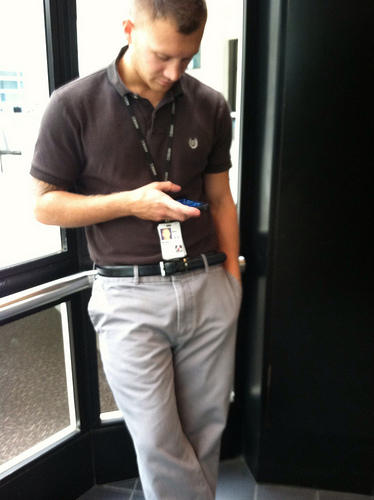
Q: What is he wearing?
A: Trousers.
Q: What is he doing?
A: Using cellphone.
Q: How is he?
A: Standing.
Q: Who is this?
A: A man.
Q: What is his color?
A: White.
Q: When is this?
A: Daytime.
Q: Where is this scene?
A: In an office.